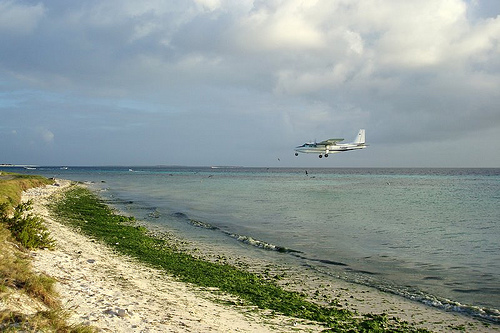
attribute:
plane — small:
[296, 129, 368, 158]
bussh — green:
[16, 215, 50, 253]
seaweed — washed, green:
[49, 181, 404, 331]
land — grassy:
[4, 172, 55, 323]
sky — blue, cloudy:
[3, 0, 499, 166]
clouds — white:
[0, 1, 499, 139]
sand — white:
[21, 177, 325, 327]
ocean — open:
[5, 165, 499, 318]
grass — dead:
[4, 176, 23, 206]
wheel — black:
[293, 152, 303, 158]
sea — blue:
[4, 165, 499, 326]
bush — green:
[7, 199, 52, 254]